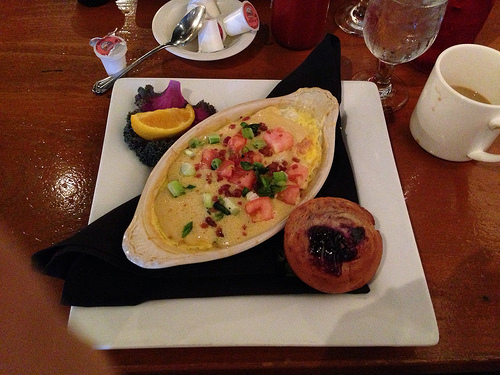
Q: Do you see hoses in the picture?
A: No, there are no hoses.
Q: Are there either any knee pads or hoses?
A: No, there are no hoses or knee pads.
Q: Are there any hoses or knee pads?
A: No, there are no hoses or knee pads.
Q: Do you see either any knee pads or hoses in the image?
A: No, there are no hoses or knee pads.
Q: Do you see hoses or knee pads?
A: No, there are no hoses or knee pads.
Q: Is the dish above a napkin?
A: Yes, the dish is above a napkin.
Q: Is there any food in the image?
A: Yes, there is food.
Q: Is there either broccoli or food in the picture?
A: Yes, there is food.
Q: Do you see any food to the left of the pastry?
A: Yes, there is food to the left of the pastry.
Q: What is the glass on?
A: The glass is on the table.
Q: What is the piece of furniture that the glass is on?
A: The piece of furniture is a table.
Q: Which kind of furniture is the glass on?
A: The glass is on the table.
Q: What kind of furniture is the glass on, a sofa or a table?
A: The glass is on a table.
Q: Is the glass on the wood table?
A: Yes, the glass is on the table.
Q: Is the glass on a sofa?
A: No, the glass is on the table.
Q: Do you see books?
A: No, there are no books.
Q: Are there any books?
A: No, there are no books.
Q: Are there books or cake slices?
A: No, there are no books or cake slices.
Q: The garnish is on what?
A: The garnish is on the plate.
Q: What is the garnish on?
A: The garnish is on the plate.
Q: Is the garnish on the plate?
A: Yes, the garnish is on the plate.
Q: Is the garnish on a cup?
A: No, the garnish is on the plate.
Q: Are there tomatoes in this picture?
A: Yes, there is a tomato.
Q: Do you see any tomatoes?
A: Yes, there is a tomato.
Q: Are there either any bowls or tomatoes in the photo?
A: Yes, there is a tomato.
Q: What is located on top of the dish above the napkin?
A: The tomato is on top of the dish.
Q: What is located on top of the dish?
A: The tomato is on top of the dish.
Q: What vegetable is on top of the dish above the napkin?
A: The vegetable is a tomato.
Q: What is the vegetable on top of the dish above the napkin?
A: The vegetable is a tomato.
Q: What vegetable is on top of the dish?
A: The vegetable is a tomato.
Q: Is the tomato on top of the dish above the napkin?
A: Yes, the tomato is on top of the dish.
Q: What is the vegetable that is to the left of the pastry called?
A: The vegetable is a tomato.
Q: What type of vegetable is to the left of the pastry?
A: The vegetable is a tomato.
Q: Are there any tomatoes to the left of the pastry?
A: Yes, there is a tomato to the left of the pastry.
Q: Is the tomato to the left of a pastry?
A: Yes, the tomato is to the left of a pastry.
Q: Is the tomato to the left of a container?
A: No, the tomato is to the left of a pastry.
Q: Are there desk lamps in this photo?
A: No, there are no desk lamps.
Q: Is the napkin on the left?
A: Yes, the napkin is on the left of the image.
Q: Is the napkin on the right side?
A: No, the napkin is on the left of the image.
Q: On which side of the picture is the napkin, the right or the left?
A: The napkin is on the left of the image.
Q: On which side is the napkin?
A: The napkin is on the left of the image.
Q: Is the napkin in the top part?
A: Yes, the napkin is in the top of the image.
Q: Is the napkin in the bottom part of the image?
A: No, the napkin is in the top of the image.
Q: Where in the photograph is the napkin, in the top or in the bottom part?
A: The napkin is in the top of the image.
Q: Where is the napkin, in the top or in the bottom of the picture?
A: The napkin is in the top of the image.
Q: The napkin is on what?
A: The napkin is on the table.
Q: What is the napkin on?
A: The napkin is on the table.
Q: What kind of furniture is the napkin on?
A: The napkin is on the table.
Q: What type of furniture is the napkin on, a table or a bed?
A: The napkin is on a table.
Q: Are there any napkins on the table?
A: Yes, there is a napkin on the table.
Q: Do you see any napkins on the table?
A: Yes, there is a napkin on the table.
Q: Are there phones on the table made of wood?
A: No, there is a napkin on the table.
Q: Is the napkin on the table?
A: Yes, the napkin is on the table.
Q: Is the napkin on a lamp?
A: No, the napkin is on the table.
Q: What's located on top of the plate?
A: The napkin is on top of the plate.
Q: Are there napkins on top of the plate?
A: Yes, there is a napkin on top of the plate.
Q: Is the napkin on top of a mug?
A: No, the napkin is on top of the plate.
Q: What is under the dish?
A: The napkin is under the dish.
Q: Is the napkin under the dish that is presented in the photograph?
A: Yes, the napkin is under the dish.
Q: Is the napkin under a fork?
A: No, the napkin is under the dish.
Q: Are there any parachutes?
A: No, there are no parachutes.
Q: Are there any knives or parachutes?
A: No, there are no parachutes or knives.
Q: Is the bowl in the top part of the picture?
A: Yes, the bowl is in the top of the image.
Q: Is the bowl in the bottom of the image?
A: No, the bowl is in the top of the image.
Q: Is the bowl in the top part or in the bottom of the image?
A: The bowl is in the top of the image.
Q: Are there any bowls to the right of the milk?
A: Yes, there is a bowl to the right of the milk.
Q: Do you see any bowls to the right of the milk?
A: Yes, there is a bowl to the right of the milk.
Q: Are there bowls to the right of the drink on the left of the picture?
A: Yes, there is a bowl to the right of the milk.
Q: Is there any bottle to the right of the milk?
A: No, there is a bowl to the right of the milk.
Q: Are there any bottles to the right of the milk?
A: No, there is a bowl to the right of the milk.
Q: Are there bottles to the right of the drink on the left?
A: No, there is a bowl to the right of the milk.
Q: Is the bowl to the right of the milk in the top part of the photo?
A: Yes, the bowl is to the right of the milk.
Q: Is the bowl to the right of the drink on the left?
A: Yes, the bowl is to the right of the milk.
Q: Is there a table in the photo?
A: Yes, there is a table.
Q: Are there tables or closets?
A: Yes, there is a table.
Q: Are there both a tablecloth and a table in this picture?
A: No, there is a table but no tablecloths.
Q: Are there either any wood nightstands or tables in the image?
A: Yes, there is a wood table.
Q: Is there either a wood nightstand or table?
A: Yes, there is a wood table.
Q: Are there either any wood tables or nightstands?
A: Yes, there is a wood table.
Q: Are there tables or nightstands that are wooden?
A: Yes, the table is wooden.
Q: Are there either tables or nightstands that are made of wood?
A: Yes, the table is made of wood.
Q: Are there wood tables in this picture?
A: Yes, there is a wood table.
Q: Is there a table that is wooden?
A: Yes, there is a table that is wooden.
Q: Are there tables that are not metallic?
A: Yes, there is a wooden table.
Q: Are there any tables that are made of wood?
A: Yes, there is a table that is made of wood.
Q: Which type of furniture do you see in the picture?
A: The furniture is a table.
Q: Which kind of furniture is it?
A: The piece of furniture is a table.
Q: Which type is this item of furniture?
A: This is a table.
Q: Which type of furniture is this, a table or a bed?
A: This is a table.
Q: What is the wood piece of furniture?
A: The piece of furniture is a table.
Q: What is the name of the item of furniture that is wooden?
A: The piece of furniture is a table.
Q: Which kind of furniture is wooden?
A: The furniture is a table.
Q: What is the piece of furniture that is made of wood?
A: The piece of furniture is a table.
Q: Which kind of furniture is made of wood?
A: The furniture is a table.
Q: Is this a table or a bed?
A: This is a table.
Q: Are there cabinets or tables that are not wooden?
A: No, there is a table but it is wooden.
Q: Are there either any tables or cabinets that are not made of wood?
A: No, there is a table but it is made of wood.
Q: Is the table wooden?
A: Yes, the table is wooden.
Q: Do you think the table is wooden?
A: Yes, the table is wooden.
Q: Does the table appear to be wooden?
A: Yes, the table is wooden.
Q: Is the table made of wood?
A: Yes, the table is made of wood.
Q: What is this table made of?
A: The table is made of wood.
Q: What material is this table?
A: The table is made of wood.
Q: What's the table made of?
A: The table is made of wood.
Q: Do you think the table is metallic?
A: No, the table is wooden.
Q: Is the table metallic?
A: No, the table is wooden.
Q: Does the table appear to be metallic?
A: No, the table is wooden.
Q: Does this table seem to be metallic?
A: No, the table is wooden.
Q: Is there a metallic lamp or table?
A: No, there is a table but it is wooden.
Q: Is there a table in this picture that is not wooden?
A: No, there is a table but it is wooden.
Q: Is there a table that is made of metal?
A: No, there is a table but it is made of wood.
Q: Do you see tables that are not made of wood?
A: No, there is a table but it is made of wood.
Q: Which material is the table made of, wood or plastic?
A: The table is made of wood.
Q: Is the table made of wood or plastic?
A: The table is made of wood.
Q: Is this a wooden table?
A: Yes, this is a wooden table.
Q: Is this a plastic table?
A: No, this is a wooden table.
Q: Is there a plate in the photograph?
A: Yes, there is a plate.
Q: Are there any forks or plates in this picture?
A: Yes, there is a plate.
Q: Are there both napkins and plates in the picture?
A: Yes, there are both a plate and a napkin.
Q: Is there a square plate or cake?
A: Yes, there is a square plate.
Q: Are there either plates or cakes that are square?
A: Yes, the plate is square.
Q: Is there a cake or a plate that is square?
A: Yes, the plate is square.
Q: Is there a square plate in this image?
A: Yes, there is a square plate.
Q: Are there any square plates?
A: Yes, there is a square plate.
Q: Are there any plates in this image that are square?
A: Yes, there is a plate that is square.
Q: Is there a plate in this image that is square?
A: Yes, there is a plate that is square.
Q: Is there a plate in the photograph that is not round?
A: Yes, there is a square plate.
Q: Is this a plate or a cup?
A: This is a plate.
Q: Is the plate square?
A: Yes, the plate is square.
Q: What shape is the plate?
A: The plate is square.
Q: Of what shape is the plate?
A: The plate is square.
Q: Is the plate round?
A: No, the plate is square.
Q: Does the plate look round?
A: No, the plate is square.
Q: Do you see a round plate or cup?
A: No, there is a plate but it is square.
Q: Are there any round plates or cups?
A: No, there is a plate but it is square.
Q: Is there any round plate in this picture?
A: No, there is a plate but it is square.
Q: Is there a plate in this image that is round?
A: No, there is a plate but it is square.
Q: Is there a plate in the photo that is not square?
A: No, there is a plate but it is square.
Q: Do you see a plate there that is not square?
A: No, there is a plate but it is square.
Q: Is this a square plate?
A: Yes, this is a square plate.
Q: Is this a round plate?
A: No, this is a square plate.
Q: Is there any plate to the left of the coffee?
A: Yes, there is a plate to the left of the coffee.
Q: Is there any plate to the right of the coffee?
A: No, the plate is to the left of the coffee.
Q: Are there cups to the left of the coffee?
A: No, there is a plate to the left of the coffee.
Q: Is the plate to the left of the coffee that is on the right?
A: Yes, the plate is to the left of the coffee.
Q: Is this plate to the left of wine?
A: No, the plate is to the left of the coffee.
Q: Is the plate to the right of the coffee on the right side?
A: No, the plate is to the left of the coffee.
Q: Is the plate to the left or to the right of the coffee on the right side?
A: The plate is to the left of the coffee.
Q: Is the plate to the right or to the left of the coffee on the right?
A: The plate is to the left of the coffee.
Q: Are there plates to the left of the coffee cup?
A: Yes, there is a plate to the left of the coffee cup.